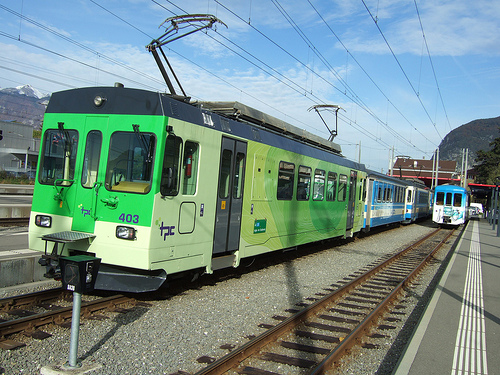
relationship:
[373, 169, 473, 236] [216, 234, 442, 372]
train on tracks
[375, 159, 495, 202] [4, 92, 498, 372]
roof of train station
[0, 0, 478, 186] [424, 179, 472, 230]
power lines hang above train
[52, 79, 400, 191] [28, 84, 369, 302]
black top on green train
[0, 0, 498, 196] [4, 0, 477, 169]
blue sky with clouds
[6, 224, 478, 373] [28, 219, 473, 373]
tracks surrounded by gravel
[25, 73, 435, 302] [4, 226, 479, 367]
commuter train on track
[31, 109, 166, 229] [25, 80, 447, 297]
front of train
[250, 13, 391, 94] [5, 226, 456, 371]
wires above train tracks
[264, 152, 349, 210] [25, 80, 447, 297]
windows on side of train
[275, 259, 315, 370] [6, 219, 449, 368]
shadow on gray gravel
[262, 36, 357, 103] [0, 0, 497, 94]
white clouds in blue sky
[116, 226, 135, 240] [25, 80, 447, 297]
headlight on front of train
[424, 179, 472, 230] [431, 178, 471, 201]
train with blue top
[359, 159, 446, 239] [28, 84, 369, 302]
train car behind green train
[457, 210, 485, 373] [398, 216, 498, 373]
white lines on pedestrian walkway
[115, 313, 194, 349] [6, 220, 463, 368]
grey gravels between railroad tracks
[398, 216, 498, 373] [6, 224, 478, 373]
pedestrian walkway beside tracks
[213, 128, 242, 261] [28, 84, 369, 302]
doors on side of green train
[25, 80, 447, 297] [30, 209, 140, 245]
train has headlights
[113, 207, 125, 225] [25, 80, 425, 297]
number 4 on train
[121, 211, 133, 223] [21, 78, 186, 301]
0 on trolley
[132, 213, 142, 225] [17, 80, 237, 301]
number 3 on trolley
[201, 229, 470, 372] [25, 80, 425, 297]
tracks next train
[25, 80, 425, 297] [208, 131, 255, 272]
train has doors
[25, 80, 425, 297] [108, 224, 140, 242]
train has headlight